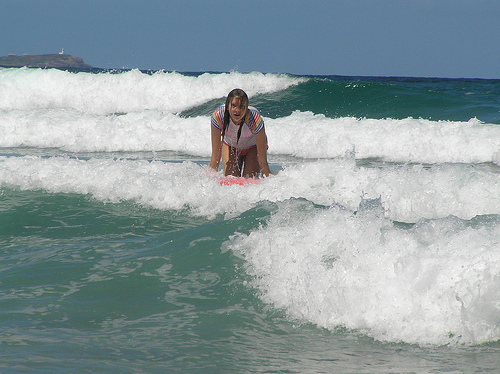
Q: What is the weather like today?
A: It is cloudless.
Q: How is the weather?
A: It is cloudless.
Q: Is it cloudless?
A: Yes, it is cloudless.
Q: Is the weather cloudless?
A: Yes, it is cloudless.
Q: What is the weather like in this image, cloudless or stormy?
A: It is cloudless.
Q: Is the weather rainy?
A: No, it is cloudless.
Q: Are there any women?
A: Yes, there is a woman.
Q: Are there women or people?
A: Yes, there is a woman.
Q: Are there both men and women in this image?
A: No, there is a woman but no men.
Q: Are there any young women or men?
A: Yes, there is a young woman.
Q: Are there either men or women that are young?
A: Yes, the woman is young.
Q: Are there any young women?
A: Yes, there is a young woman.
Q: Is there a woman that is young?
A: Yes, there is a woman that is young.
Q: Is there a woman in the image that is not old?
A: Yes, there is an young woman.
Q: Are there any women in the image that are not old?
A: Yes, there is an young woman.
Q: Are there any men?
A: No, there are no men.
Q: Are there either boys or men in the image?
A: No, there are no men or boys.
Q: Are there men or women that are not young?
A: No, there is a woman but she is young.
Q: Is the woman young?
A: Yes, the woman is young.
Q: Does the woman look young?
A: Yes, the woman is young.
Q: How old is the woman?
A: The woman is young.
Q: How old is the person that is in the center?
A: The woman is young.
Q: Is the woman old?
A: No, the woman is young.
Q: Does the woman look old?
A: No, the woman is young.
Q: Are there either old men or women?
A: No, there is a woman but she is young.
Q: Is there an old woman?
A: No, there is a woman but she is young.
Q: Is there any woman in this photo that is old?
A: No, there is a woman but she is young.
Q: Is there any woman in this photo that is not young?
A: No, there is a woman but she is young.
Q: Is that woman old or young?
A: The woman is young.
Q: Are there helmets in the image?
A: No, there are no helmets.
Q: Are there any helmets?
A: No, there are no helmets.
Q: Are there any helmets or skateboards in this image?
A: No, there are no helmets or skateboards.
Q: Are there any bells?
A: No, there are no bells.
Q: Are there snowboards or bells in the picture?
A: No, there are no bells or snowboards.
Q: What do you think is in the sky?
A: The clouds are in the sky.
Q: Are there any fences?
A: No, there are no fences.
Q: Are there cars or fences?
A: No, there are no fences or cars.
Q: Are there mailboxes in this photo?
A: No, there are no mailboxes.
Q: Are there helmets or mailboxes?
A: No, there are no mailboxes or helmets.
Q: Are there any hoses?
A: No, there are no hoses.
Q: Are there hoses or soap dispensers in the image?
A: No, there are no hoses or soap dispensers.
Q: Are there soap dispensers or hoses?
A: No, there are no hoses or soap dispensers.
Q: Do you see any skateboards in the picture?
A: No, there are no skateboards.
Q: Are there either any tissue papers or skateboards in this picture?
A: No, there are no skateboards or tissue papers.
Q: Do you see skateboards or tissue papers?
A: No, there are no skateboards or tissue papers.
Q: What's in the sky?
A: The clouds are in the sky.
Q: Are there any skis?
A: No, there are no skis.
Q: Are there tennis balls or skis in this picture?
A: No, there are no skis or tennis balls.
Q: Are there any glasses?
A: No, there are no glasses.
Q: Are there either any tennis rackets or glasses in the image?
A: No, there are no glasses or tennis rackets.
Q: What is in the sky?
A: The clouds are in the sky.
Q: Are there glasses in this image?
A: No, there are no glasses.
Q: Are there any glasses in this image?
A: No, there are no glasses.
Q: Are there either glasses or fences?
A: No, there are no glasses or fences.